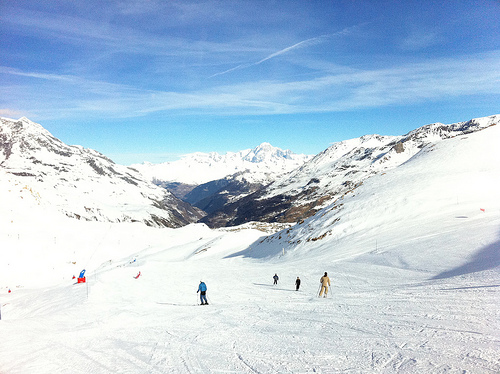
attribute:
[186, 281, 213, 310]
person — skiing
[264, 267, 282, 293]
person — skiing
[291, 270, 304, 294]
person — skiing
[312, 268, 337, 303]
person — skiing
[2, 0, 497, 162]
sky — blue, clear, bluee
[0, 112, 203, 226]
hill — snowy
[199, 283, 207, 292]
jacket — blue, black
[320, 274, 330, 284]
jacket — yellow, beige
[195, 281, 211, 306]
person — skiing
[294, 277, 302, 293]
person — skiing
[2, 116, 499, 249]
mountain — snowy, white, rocky, tall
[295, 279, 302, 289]
clothes — dark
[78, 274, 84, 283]
marker — red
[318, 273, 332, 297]
person — skiing, walking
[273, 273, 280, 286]
person — skiing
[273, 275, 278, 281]
man — skiing, skating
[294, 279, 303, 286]
jacket — black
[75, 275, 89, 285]
bench — red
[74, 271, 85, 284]
flag — red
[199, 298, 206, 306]
shoe — black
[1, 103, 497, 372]
snow — white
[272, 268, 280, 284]
person — skiing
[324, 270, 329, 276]
mask — black